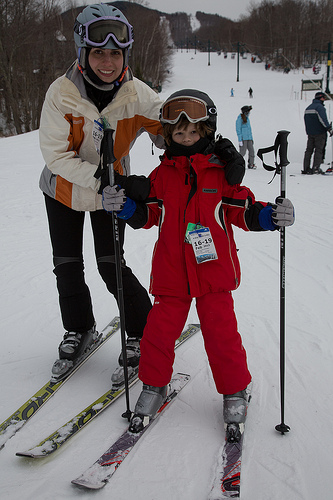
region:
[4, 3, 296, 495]
Instructor teaching child to ski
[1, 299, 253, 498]
people have skis on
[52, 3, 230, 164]
Both people have skis on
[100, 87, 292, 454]
Child is wearing a snowsuit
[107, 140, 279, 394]
The snowsuit is red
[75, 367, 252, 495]
The childs skis are grey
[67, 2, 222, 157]
Both people are wearing safety gear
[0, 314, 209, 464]
Woman has yellow skis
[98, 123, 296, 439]
Ski poles are black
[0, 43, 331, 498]
The snow is white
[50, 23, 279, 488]
The woman and child are skiing.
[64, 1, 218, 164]
The woman and child are wearing helmets.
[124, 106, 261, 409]
The child is wearing red.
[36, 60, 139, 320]
The woman is wearing white, black, gray and orange.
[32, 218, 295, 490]
The people are in the snow.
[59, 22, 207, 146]
The woman and child have goggles.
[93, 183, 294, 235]
The child is wearing gray gloves.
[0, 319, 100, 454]
The woman is wearing yellow and gray skis.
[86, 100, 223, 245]
The woman is helping the child stand up.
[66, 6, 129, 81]
The woman is smiling.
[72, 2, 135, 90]
Helmet on woman's head.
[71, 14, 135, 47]
Goggles on woman's helmet.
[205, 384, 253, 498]
Ski on boy's foot.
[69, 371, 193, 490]
Ski on boy's foot.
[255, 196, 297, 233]
Glove on boy's hand.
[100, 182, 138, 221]
Glove on boy's hand.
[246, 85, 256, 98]
Skier in the background.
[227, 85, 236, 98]
Skier in the background.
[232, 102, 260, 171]
Skier in the background.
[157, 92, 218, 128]
Goggles on boy's head.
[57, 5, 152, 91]
Smiling woman with helmet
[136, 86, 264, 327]
Child wearing red snow suit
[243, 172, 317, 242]
Gloved hand holding ski stick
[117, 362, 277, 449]
Grey boots lodged in snow skis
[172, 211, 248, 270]
Ski tags worn on red snow suit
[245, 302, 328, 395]
Ski tracks in the snow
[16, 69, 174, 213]
White jacket with orange accents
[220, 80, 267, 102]
People skiing far away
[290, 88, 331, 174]
Man wearing dark blue coat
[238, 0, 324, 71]
Leafless trees in winter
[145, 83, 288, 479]
boy wearing red snow suit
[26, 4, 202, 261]
lady wearing cream and orange jacket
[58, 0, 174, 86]
lady wearing grey helmet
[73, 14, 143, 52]
lady wearing purple googles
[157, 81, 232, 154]
boy wearing black helmet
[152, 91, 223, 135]
boy wearing silver and orange googles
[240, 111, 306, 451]
black ski stick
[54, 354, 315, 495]
boy on red and silver skies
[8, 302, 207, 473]
lady on green and silver skies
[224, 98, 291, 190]
lady wearing a blue jacket